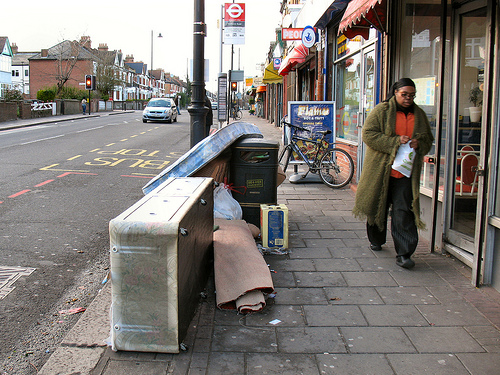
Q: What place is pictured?
A: It is a sidewalk.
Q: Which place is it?
A: It is a sidewalk.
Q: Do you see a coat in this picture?
A: Yes, there is a coat.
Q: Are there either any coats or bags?
A: Yes, there is a coat.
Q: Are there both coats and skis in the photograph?
A: No, there is a coat but no skis.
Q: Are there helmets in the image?
A: No, there are no helmets.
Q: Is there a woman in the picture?
A: Yes, there is a woman.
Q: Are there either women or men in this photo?
A: Yes, there is a woman.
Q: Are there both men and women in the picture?
A: No, there is a woman but no men.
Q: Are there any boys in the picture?
A: No, there are no boys.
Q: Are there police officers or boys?
A: No, there are no boys or police officers.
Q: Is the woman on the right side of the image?
A: Yes, the woman is on the right of the image.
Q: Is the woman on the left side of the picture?
A: No, the woman is on the right of the image.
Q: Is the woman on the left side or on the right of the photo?
A: The woman is on the right of the image.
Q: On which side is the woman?
A: The woman is on the right of the image.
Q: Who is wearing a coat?
A: The woman is wearing a coat.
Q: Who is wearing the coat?
A: The woman is wearing a coat.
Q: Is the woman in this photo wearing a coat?
A: Yes, the woman is wearing a coat.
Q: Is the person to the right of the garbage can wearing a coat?
A: Yes, the woman is wearing a coat.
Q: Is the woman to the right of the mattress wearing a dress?
A: No, the woman is wearing a coat.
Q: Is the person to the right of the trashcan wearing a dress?
A: No, the woman is wearing a coat.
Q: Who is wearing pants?
A: The woman is wearing pants.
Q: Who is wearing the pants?
A: The woman is wearing pants.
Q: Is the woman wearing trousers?
A: Yes, the woman is wearing trousers.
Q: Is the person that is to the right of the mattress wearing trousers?
A: Yes, the woman is wearing trousers.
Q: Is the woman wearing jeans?
A: No, the woman is wearing trousers.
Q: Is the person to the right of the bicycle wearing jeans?
A: No, the woman is wearing trousers.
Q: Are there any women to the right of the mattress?
A: Yes, there is a woman to the right of the mattress.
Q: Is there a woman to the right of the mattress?
A: Yes, there is a woman to the right of the mattress.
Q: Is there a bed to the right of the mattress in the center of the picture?
A: No, there is a woman to the right of the mattress.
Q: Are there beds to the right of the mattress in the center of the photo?
A: No, there is a woman to the right of the mattress.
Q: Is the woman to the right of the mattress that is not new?
A: Yes, the woman is to the right of the mattress.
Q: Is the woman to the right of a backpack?
A: No, the woman is to the right of the mattress.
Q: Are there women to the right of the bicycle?
A: Yes, there is a woman to the right of the bicycle.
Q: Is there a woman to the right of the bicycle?
A: Yes, there is a woman to the right of the bicycle.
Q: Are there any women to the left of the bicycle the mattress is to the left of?
A: No, the woman is to the right of the bicycle.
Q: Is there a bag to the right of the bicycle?
A: No, there is a woman to the right of the bicycle.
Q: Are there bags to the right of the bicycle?
A: No, there is a woman to the right of the bicycle.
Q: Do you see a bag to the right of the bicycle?
A: No, there is a woman to the right of the bicycle.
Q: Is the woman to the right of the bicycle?
A: Yes, the woman is to the right of the bicycle.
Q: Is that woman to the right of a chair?
A: No, the woman is to the right of the bicycle.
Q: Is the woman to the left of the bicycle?
A: No, the woman is to the right of the bicycle.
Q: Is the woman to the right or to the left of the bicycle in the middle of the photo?
A: The woman is to the right of the bicycle.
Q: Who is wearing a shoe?
A: The woman is wearing a shoe.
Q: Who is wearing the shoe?
A: The woman is wearing a shoe.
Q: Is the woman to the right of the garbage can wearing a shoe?
A: Yes, the woman is wearing a shoe.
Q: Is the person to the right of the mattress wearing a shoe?
A: Yes, the woman is wearing a shoe.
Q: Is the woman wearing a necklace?
A: No, the woman is wearing a shoe.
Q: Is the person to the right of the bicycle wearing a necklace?
A: No, the woman is wearing a shoe.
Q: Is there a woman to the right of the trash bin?
A: Yes, there is a woman to the right of the trash bin.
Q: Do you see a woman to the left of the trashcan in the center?
A: No, the woman is to the right of the garbage bin.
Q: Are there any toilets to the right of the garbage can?
A: No, there is a woman to the right of the garbage can.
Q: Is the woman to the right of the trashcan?
A: Yes, the woman is to the right of the trashcan.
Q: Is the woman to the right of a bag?
A: No, the woman is to the right of the trashcan.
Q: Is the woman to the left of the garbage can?
A: No, the woman is to the right of the garbage can.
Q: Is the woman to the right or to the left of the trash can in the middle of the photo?
A: The woman is to the right of the trash can.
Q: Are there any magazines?
A: No, there are no magazines.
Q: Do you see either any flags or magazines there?
A: No, there are no magazines or flags.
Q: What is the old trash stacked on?
A: The litter is stacked on the sidewalk.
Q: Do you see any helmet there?
A: No, there are no helmets.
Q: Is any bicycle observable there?
A: Yes, there is a bicycle.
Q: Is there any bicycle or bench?
A: Yes, there is a bicycle.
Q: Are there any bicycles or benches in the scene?
A: Yes, there is a bicycle.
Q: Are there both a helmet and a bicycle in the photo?
A: No, there is a bicycle but no helmets.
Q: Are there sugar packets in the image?
A: No, there are no sugar packets.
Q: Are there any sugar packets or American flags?
A: No, there are no sugar packets or American flags.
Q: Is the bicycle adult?
A: Yes, the bicycle is adult.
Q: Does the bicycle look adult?
A: Yes, the bicycle is adult.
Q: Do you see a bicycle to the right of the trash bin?
A: Yes, there is a bicycle to the right of the trash bin.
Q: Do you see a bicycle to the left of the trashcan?
A: No, the bicycle is to the right of the trashcan.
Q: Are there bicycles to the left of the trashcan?
A: No, the bicycle is to the right of the trashcan.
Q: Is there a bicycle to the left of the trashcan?
A: No, the bicycle is to the right of the trashcan.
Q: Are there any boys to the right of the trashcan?
A: No, there is a bicycle to the right of the trashcan.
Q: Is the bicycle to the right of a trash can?
A: Yes, the bicycle is to the right of a trash can.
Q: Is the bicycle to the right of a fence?
A: No, the bicycle is to the right of a trash can.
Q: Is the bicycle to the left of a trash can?
A: No, the bicycle is to the right of a trash can.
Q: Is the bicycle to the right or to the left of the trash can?
A: The bicycle is to the right of the trash can.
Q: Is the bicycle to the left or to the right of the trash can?
A: The bicycle is to the right of the trash can.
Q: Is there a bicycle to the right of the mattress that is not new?
A: Yes, there is a bicycle to the right of the mattress.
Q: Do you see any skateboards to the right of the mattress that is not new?
A: No, there is a bicycle to the right of the mattress.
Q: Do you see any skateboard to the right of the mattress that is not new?
A: No, there is a bicycle to the right of the mattress.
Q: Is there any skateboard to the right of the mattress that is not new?
A: No, there is a bicycle to the right of the mattress.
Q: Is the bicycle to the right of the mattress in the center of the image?
A: Yes, the bicycle is to the right of the mattress.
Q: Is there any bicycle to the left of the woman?
A: Yes, there is a bicycle to the left of the woman.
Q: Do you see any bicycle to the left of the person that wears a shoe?
A: Yes, there is a bicycle to the left of the woman.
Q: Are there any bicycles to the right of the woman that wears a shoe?
A: No, the bicycle is to the left of the woman.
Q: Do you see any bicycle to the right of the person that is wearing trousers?
A: No, the bicycle is to the left of the woman.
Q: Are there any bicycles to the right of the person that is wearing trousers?
A: No, the bicycle is to the left of the woman.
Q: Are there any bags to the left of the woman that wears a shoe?
A: No, there is a bicycle to the left of the woman.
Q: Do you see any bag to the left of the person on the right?
A: No, there is a bicycle to the left of the woman.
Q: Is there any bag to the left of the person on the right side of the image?
A: No, there is a bicycle to the left of the woman.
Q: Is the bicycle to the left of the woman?
A: Yes, the bicycle is to the left of the woman.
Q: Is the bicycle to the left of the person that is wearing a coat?
A: Yes, the bicycle is to the left of the woman.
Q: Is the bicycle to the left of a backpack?
A: No, the bicycle is to the left of the woman.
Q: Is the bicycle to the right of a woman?
A: No, the bicycle is to the left of a woman.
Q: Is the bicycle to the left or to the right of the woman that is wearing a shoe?
A: The bicycle is to the left of the woman.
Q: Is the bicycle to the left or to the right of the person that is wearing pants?
A: The bicycle is to the left of the woman.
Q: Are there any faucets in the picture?
A: No, there are no faucets.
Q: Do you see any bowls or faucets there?
A: No, there are no faucets or bowls.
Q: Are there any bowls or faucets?
A: No, there are no faucets or bowls.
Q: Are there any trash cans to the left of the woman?
A: Yes, there is a trash can to the left of the woman.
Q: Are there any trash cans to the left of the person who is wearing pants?
A: Yes, there is a trash can to the left of the woman.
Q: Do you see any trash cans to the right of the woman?
A: No, the trash can is to the left of the woman.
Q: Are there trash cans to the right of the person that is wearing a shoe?
A: No, the trash can is to the left of the woman.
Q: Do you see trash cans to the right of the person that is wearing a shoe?
A: No, the trash can is to the left of the woman.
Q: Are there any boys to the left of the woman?
A: No, there is a trash can to the left of the woman.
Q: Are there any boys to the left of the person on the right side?
A: No, there is a trash can to the left of the woman.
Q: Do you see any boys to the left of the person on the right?
A: No, there is a trash can to the left of the woman.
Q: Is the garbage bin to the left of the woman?
A: Yes, the garbage bin is to the left of the woman.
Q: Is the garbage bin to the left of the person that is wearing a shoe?
A: Yes, the garbage bin is to the left of the woman.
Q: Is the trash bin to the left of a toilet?
A: No, the trash bin is to the left of the woman.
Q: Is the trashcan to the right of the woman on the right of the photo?
A: No, the trashcan is to the left of the woman.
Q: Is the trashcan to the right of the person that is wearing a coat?
A: No, the trashcan is to the left of the woman.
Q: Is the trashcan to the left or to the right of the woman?
A: The trashcan is to the left of the woman.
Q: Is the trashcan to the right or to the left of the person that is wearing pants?
A: The trashcan is to the left of the woman.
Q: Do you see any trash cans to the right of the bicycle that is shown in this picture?
A: No, the trash can is to the left of the bicycle.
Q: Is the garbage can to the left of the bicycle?
A: Yes, the garbage can is to the left of the bicycle.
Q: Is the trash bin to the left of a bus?
A: No, the trash bin is to the left of the bicycle.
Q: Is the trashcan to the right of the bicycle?
A: No, the trashcan is to the left of the bicycle.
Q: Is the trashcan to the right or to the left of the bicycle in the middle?
A: The trashcan is to the left of the bicycle.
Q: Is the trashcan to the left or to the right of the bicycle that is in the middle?
A: The trashcan is to the left of the bicycle.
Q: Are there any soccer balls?
A: No, there are no soccer balls.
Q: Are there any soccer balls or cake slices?
A: No, there are no soccer balls or cake slices.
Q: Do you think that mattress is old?
A: Yes, the mattress is old.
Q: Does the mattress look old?
A: Yes, the mattress is old.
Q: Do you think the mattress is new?
A: No, the mattress is old.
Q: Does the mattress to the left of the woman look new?
A: No, the mattress is old.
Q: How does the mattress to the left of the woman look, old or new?
A: The mattress is old.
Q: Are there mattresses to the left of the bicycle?
A: Yes, there is a mattress to the left of the bicycle.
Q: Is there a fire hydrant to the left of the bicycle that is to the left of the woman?
A: No, there is a mattress to the left of the bicycle.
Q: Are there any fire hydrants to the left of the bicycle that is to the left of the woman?
A: No, there is a mattress to the left of the bicycle.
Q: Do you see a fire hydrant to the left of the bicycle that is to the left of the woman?
A: No, there is a mattress to the left of the bicycle.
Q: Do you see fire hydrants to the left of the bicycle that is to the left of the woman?
A: No, there is a mattress to the left of the bicycle.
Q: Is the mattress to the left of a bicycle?
A: Yes, the mattress is to the left of a bicycle.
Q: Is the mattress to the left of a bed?
A: No, the mattress is to the left of a bicycle.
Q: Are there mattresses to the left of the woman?
A: Yes, there is a mattress to the left of the woman.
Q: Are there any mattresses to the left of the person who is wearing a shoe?
A: Yes, there is a mattress to the left of the woman.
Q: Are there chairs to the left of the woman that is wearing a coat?
A: No, there is a mattress to the left of the woman.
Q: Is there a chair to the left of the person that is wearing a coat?
A: No, there is a mattress to the left of the woman.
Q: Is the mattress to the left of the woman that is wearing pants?
A: Yes, the mattress is to the left of the woman.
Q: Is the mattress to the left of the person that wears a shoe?
A: Yes, the mattress is to the left of the woman.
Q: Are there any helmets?
A: No, there are no helmets.